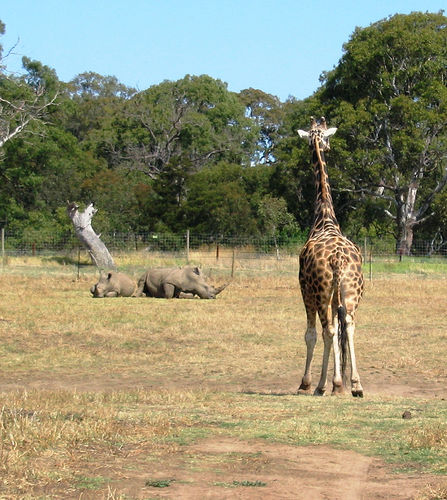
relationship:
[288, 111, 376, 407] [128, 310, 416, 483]
giraffe in a field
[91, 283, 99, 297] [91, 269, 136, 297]
rhino horn of a rhino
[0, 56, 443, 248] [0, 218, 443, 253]
trees and bush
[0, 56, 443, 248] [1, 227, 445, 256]
trees behind a fence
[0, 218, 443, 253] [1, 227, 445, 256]
bush behind a fence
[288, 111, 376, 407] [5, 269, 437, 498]
giraffe in field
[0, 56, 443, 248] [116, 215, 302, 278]
trees behind fence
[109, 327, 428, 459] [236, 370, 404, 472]
grass in field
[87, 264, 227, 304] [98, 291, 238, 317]
rhino in grass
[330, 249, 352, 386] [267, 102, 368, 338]
tail of giraffe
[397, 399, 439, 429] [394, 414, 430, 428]
stone of grass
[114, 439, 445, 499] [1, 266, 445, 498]
bald spot on grass area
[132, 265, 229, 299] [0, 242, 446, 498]
hippo on grass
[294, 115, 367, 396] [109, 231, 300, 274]
animal in an enclosure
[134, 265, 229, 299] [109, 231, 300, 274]
animal in an enclosure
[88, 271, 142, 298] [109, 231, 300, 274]
animal in an enclosure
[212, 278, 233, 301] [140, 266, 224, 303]
horn of rhino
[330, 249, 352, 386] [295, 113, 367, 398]
tail of giraffe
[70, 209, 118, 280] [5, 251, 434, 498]
tree trunk in ground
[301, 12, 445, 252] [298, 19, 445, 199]
tree with leaves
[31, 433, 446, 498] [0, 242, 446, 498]
dirt near grass